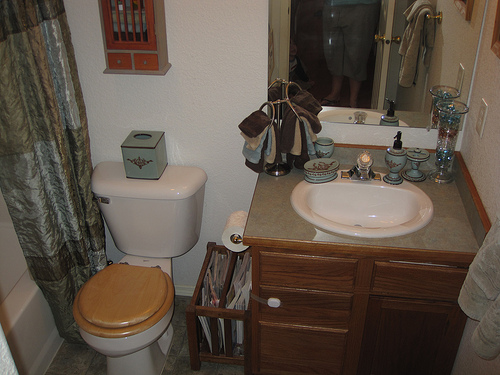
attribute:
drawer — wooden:
[240, 237, 477, 374]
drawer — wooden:
[257, 284, 359, 329]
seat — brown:
[70, 261, 175, 338]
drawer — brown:
[251, 249, 358, 301]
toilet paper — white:
[223, 209, 249, 252]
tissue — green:
[119, 127, 169, 180]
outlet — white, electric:
[448, 61, 492, 138]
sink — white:
[288, 166, 434, 239]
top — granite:
[242, 142, 480, 252]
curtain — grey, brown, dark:
[0, 1, 108, 346]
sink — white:
[283, 148, 442, 241]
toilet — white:
[69, 159, 207, 374]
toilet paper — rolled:
[204, 185, 252, 258]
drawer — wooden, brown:
[369, 256, 484, 306]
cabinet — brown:
[239, 236, 481, 372]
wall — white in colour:
[68, 0, 268, 299]